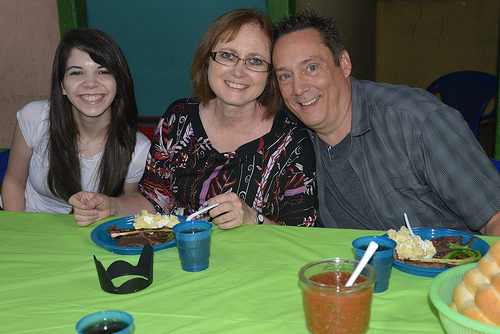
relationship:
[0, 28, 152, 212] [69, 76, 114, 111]
lady has face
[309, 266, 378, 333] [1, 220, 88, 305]
bowl on table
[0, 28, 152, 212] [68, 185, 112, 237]
lady has wrist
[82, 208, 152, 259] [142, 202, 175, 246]
plate of food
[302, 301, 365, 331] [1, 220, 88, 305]
salsa on table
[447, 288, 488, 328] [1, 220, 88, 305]
basket on table